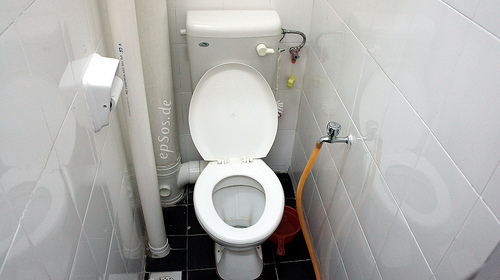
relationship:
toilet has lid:
[179, 8, 284, 280] [189, 61, 278, 158]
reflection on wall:
[341, 14, 450, 269] [289, 0, 498, 276]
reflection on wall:
[0, 69, 75, 278] [1, 2, 154, 280]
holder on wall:
[82, 44, 128, 137] [1, 2, 154, 280]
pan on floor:
[270, 203, 303, 259] [145, 169, 316, 278]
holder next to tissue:
[82, 44, 128, 137] [108, 76, 128, 114]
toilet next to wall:
[179, 8, 284, 280] [289, 0, 498, 276]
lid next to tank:
[189, 61, 278, 158] [180, 5, 283, 71]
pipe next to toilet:
[107, 0, 185, 251] [179, 8, 284, 280]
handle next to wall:
[257, 37, 278, 62] [289, 0, 498, 276]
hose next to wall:
[295, 142, 323, 279] [289, 0, 498, 276]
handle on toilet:
[257, 37, 278, 62] [179, 8, 284, 280]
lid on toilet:
[189, 61, 278, 158] [179, 8, 284, 280]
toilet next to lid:
[179, 8, 284, 280] [189, 61, 278, 158]